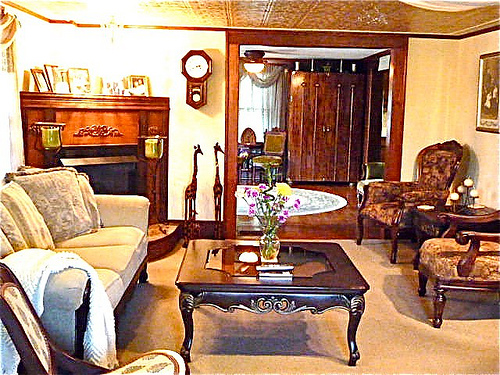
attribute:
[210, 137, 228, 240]
statue — giraffes 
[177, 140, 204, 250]
statue — giraffes 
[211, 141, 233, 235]
giraffe statue — brown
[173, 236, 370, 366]
table — wooden 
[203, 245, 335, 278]
insert — glass 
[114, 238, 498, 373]
carpeting — tan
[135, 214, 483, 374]
floor — dark , wood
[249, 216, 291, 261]
vase — clear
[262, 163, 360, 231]
flowers — yellow and purple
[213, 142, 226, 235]
statue — decorative giraffe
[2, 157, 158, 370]
couch — off white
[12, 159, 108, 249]
pillows — big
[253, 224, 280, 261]
vase — glass 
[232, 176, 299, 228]
flowers — purple, yellow 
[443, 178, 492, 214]
candles — round and yellow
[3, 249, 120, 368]
blanket —  white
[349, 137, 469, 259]
armchair — brown patterned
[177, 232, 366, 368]
coffee table — wood, elaborate, glass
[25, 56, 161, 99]
family photos — framed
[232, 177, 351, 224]
rug — oval , white , blue 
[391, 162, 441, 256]
framed — dark, brown and wooden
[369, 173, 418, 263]
arm chair — brown and tan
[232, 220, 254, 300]
candles — round and white